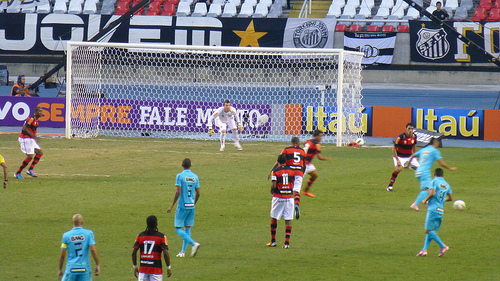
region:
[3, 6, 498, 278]
people playing in a soccer game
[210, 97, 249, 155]
a goalie in a soccer game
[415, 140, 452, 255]
light blue soccer uniforms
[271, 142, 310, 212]
red and black striped soccer uniforms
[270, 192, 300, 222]
white soccer shorts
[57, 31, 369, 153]
a soccer net on a field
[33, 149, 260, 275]
green grass in a soccer field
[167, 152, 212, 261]
a man on a soccer field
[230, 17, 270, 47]
a star on a banner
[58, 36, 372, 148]
a white soccer net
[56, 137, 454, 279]
four players wearing blue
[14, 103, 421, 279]
six players wearing red and white uniforms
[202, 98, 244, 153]
goalie dressed in white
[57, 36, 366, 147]
goalie in a large, white net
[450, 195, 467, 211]
soccer play near player in blue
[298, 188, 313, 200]
player wearing orange shoes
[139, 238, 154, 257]
player with a "17" on his jersey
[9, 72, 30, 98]
two spectators watching from near the net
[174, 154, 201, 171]
head of a person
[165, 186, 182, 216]
arm of a person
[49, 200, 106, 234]
head of a person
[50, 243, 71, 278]
arm of a person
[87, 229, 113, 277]
arm of a person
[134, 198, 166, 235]
head of a person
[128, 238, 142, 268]
arm of a person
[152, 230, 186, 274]
arm of a person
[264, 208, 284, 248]
leg of a person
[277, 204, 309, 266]
leg of a person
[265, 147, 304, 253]
player on the field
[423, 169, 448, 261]
player on the field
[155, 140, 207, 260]
player on the field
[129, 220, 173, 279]
player on the field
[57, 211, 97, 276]
player on the field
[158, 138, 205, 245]
player on the field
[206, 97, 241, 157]
player on the field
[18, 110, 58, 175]
player on the field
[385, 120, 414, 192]
player on the field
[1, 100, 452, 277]
men playing soccer on a field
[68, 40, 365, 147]
a white soccer field net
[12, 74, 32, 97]
a man operating a camera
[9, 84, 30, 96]
an orange security vest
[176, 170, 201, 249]
man wearing a light blue uniform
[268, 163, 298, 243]
man wearing a white, red and black uniform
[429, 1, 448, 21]
a man staning in the bleachers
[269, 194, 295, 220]
man wearing white shorts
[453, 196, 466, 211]
a white soccer ball on a field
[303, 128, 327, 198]
a man running toward a soccer ball